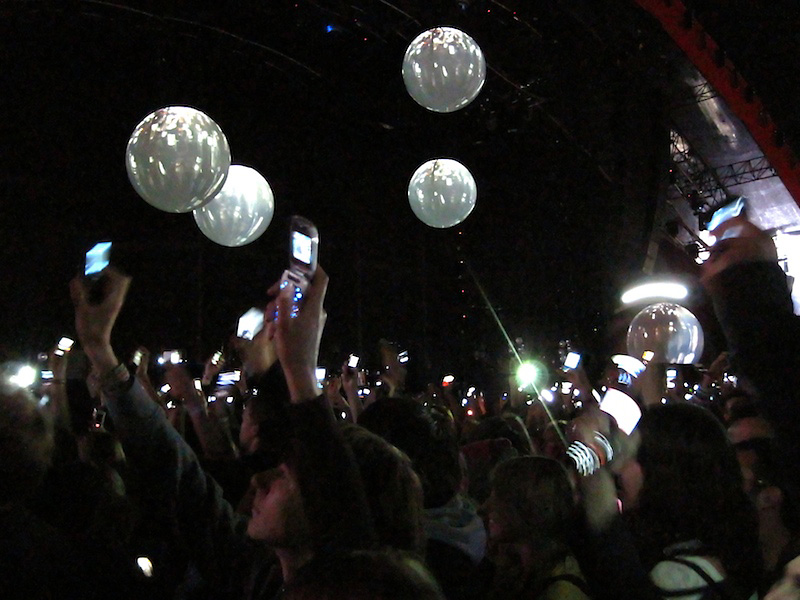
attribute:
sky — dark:
[3, 9, 798, 362]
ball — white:
[119, 108, 234, 215]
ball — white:
[400, 153, 482, 234]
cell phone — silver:
[267, 213, 321, 334]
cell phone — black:
[74, 239, 120, 305]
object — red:
[639, 7, 799, 204]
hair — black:
[649, 400, 739, 561]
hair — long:
[644, 400, 756, 593]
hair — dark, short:
[365, 405, 458, 492]